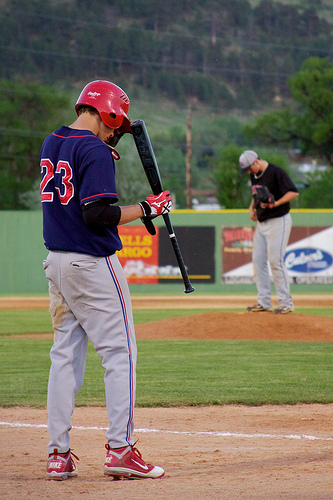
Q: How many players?
A: 2.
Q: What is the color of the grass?
A: Green.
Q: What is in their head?
A: Helmet.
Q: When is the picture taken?
A: Daytime.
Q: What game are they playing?
A: Baseball.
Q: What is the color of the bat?
A: Black.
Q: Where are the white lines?
A: In the ground.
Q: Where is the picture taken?
A: At a ballgame.